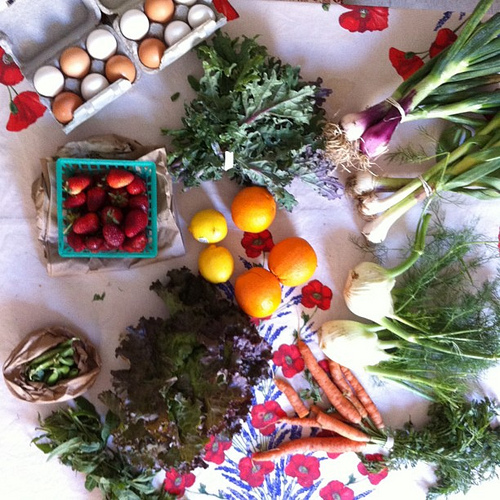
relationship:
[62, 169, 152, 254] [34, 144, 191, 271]
strawberries are on paper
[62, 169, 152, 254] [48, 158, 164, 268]
strawberries in a box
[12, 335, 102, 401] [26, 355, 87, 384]
bag has beans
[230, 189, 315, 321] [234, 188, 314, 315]
oranges are in threes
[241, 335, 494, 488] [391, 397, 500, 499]
carrots greens are leafy